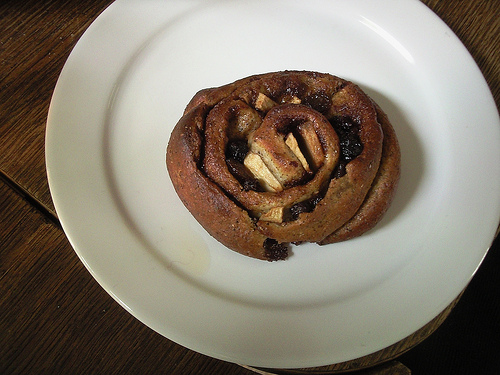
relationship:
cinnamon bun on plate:
[163, 66, 403, 262] [39, 2, 483, 362]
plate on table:
[39, 2, 483, 362] [1, 3, 481, 372]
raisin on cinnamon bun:
[223, 134, 247, 165] [163, 66, 403, 263]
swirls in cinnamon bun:
[194, 87, 358, 213] [163, 66, 403, 262]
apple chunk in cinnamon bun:
[238, 152, 287, 194] [163, 66, 403, 262]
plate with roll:
[39, 2, 483, 362] [161, 67, 402, 259]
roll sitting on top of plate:
[161, 67, 402, 259] [39, 2, 483, 362]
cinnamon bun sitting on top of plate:
[163, 66, 403, 262] [39, 2, 483, 362]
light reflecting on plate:
[358, 17, 416, 66] [39, 2, 483, 362]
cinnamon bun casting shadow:
[163, 66, 403, 262] [339, 74, 426, 237]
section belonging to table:
[0, 179, 260, 373] [1, 3, 481, 372]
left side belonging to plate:
[40, 0, 170, 343] [39, 2, 483, 362]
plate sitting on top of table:
[39, 2, 483, 362] [1, 3, 481, 372]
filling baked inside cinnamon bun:
[330, 112, 363, 180] [163, 66, 403, 262]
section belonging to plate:
[156, 1, 389, 83] [39, 2, 483, 362]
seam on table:
[1, 170, 61, 225] [1, 3, 481, 372]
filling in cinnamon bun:
[241, 143, 282, 193] [163, 66, 403, 263]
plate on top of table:
[39, 2, 483, 362] [1, 3, 481, 372]